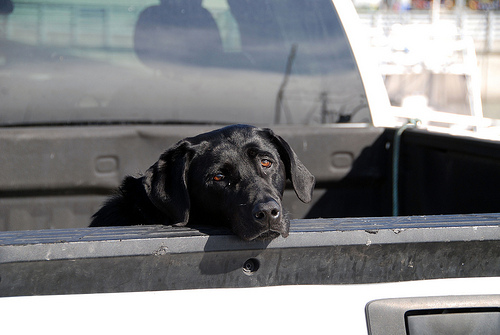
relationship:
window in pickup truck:
[1, 0, 377, 136] [0, 0, 499, 335]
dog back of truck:
[153, 117, 400, 295] [29, 23, 453, 250]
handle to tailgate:
[363, 295, 498, 334] [4, 209, 497, 331]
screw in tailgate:
[227, 260, 269, 278] [4, 209, 497, 331]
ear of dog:
[148, 145, 198, 223] [88, 125, 308, 241]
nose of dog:
[252, 201, 281, 224] [105, 116, 321, 249]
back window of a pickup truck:
[2, 6, 364, 126] [0, 0, 499, 335]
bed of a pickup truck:
[1, 127, 498, 251] [0, 135, 495, 277]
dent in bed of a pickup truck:
[131, 128, 146, 140] [0, 0, 499, 335]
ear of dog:
[144, 130, 194, 213] [87, 120, 317, 244]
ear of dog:
[268, 127, 326, 205] [142, 119, 297, 271]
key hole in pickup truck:
[239, 246, 274, 275] [0, 0, 499, 335]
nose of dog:
[252, 201, 281, 224] [99, 118, 312, 252]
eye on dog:
[255, 148, 276, 178] [95, 129, 315, 252]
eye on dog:
[204, 170, 227, 190] [95, 129, 315, 252]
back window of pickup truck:
[2, 6, 364, 126] [0, 0, 499, 335]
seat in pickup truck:
[121, 7, 277, 137] [0, 0, 499, 335]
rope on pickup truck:
[388, 118, 419, 211] [0, 0, 499, 335]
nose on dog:
[248, 197, 280, 228] [87, 120, 317, 244]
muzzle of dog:
[245, 200, 292, 242] [87, 120, 317, 244]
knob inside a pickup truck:
[327, 149, 354, 173] [0, 0, 499, 335]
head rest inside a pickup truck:
[130, 0, 230, 67] [0, 0, 499, 335]